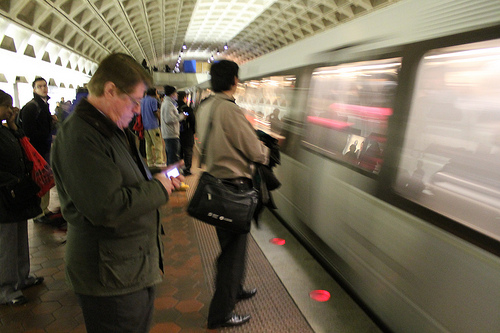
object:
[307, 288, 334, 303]
light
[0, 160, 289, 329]
ground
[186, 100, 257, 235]
shoulder bag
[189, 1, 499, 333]
train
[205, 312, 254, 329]
shoe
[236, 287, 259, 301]
shoe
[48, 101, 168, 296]
jacket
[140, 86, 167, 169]
man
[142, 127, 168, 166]
pants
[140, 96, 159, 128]
shirt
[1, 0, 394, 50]
ceiling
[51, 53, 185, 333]
man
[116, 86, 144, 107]
glasses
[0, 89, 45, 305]
woman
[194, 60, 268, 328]
man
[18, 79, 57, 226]
person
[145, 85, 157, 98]
head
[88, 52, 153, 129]
head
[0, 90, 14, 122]
head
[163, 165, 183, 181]
cellphone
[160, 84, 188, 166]
person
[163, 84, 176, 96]
hat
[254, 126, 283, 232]
coat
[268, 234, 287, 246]
light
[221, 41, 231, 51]
lights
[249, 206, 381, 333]
stripe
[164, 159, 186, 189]
left hand